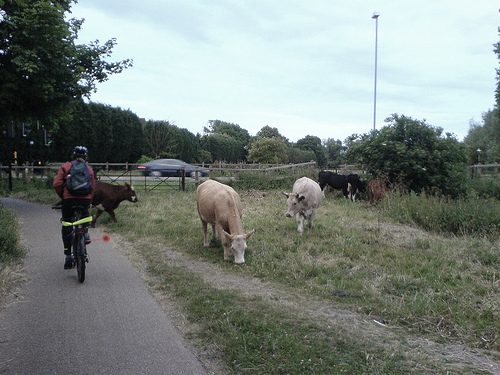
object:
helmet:
[71, 146, 88, 158]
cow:
[196, 178, 255, 265]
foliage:
[444, 174, 456, 185]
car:
[137, 158, 216, 179]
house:
[1, 97, 63, 172]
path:
[150, 232, 499, 374]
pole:
[371, 12, 379, 135]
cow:
[281, 177, 324, 238]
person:
[53, 144, 95, 269]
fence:
[1, 159, 317, 193]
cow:
[55, 179, 138, 229]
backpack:
[65, 157, 94, 196]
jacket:
[52, 158, 97, 200]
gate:
[93, 168, 182, 193]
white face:
[228, 236, 250, 265]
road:
[1, 172, 318, 182]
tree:
[340, 112, 471, 201]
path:
[1, 193, 210, 373]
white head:
[222, 228, 257, 266]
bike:
[51, 200, 94, 284]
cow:
[317, 171, 369, 204]